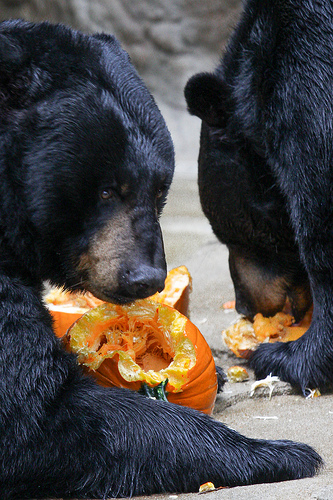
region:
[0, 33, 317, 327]
the heads of two bears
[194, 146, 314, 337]
a bear chewing on a pumpkin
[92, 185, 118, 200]
brown eye of a bear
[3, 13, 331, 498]
two large black bears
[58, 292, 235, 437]
a partially eaten pumpkin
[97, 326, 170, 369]
the stringy stuff inside pumpkin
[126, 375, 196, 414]
a green stem on the pumpkin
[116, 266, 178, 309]
a black nose of a bear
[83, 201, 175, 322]
a tan snout of bear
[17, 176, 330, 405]
two bears enjoying pumpkins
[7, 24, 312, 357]
2 bears are eating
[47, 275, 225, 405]
the pumpkin is orange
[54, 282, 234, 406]
the bear bit the pumpkin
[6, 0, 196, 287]
the bear is black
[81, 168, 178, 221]
the eyes are open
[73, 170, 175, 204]
the eyes are brown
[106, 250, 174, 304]
the nose is black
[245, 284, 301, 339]
the bear is eating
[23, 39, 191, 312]
bear is looking to the right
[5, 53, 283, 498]
the bear is wet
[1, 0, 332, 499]
two black bears enjoying a pumpkin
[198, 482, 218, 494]
tiny piece of pumpkin next to a bear's arm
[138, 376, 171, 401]
green stem on an orange pumpkin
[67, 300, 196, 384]
interior of a smashed pumpkin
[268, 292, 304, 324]
mouth of a bear eating a pumpkin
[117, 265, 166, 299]
bear's shiny black nose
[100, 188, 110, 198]
bear's small round shiny eye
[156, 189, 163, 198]
bear's small round shiny eye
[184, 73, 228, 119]
bear's round nubby ear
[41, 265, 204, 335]
pumpkin broken in half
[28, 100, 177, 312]
Face of a black bear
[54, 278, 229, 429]
pumpkin that has been destroyed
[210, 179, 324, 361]
Black bear eating a pumpkin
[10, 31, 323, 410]
Black bears at Halloween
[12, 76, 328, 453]
Bears in the zoo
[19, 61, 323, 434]
Bears eating pumpkins in a zoo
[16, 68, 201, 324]
Bear looking at the camera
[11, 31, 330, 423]
Animals celebrating Halloween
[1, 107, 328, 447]
Bears enjoying eating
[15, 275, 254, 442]
Smashed, half-eaten pumpkin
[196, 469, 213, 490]
part of a stone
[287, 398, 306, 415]
part of a ground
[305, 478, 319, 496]
part of a ground